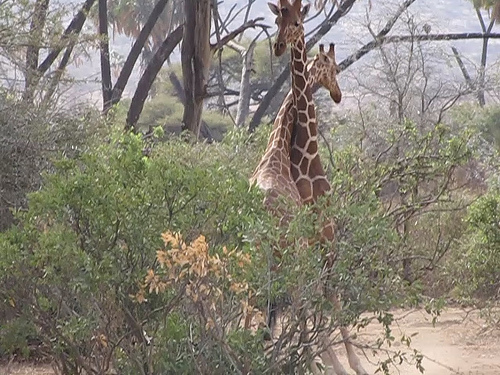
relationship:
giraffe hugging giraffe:
[270, 0, 318, 230] [249, 46, 344, 233]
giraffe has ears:
[249, 43, 342, 373] [316, 39, 337, 58]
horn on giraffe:
[329, 42, 335, 53] [291, 10, 346, 192]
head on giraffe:
[263, 2, 312, 69] [247, 24, 337, 254]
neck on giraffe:
[269, 40, 325, 172] [249, 43, 342, 373]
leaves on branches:
[17, 142, 215, 268] [15, 302, 370, 374]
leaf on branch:
[398, 119, 422, 139] [261, 234, 276, 339]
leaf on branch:
[144, 121, 167, 140] [384, 303, 423, 322]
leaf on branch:
[461, 205, 481, 228] [379, 167, 456, 228]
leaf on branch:
[123, 187, 148, 205] [167, 189, 200, 219]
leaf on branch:
[93, 258, 120, 272] [100, 217, 125, 259]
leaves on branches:
[147, 144, 264, 254] [133, 127, 257, 282]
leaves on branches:
[344, 124, 494, 254] [370, 76, 452, 246]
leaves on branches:
[345, 227, 376, 264] [383, 147, 480, 230]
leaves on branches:
[120, 141, 136, 154] [373, 131, 399, 187]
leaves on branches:
[37, 234, 75, 266] [271, 298, 323, 359]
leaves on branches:
[80, 185, 130, 224] [119, 305, 156, 365]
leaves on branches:
[149, 155, 188, 204] [6, 270, 66, 326]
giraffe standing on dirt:
[266, 0, 369, 375] [271, 303, 493, 373]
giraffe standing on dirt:
[247, 41, 345, 375] [1, 351, 59, 372]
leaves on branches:
[144, 235, 276, 328] [143, 234, 289, 374]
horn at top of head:
[318, 42, 325, 54] [306, 44, 341, 104]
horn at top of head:
[328, 41, 336, 53] [306, 44, 341, 104]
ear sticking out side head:
[266, 2, 282, 21] [259, 0, 307, 54]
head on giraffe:
[263, 0, 312, 90] [267, 0, 337, 211]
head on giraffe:
[304, 33, 350, 107] [250, 24, 412, 341]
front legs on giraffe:
[312, 283, 369, 373] [262, 0, 365, 375]